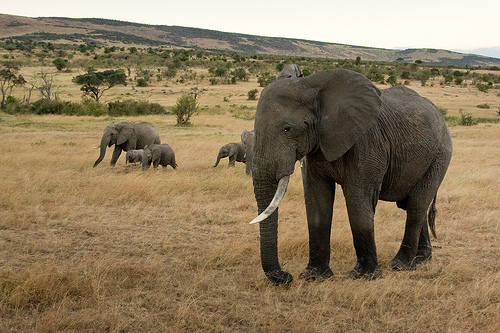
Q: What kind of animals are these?
A: Elephants.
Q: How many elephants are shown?
A: 6.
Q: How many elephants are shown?
A: Four.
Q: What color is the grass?
A: Brown.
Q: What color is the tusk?
A: White.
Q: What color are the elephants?
A: Grey.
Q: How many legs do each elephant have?
A: Four.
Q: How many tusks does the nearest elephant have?
A: One.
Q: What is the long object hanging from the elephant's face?
A: Trunk.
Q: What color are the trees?
A: Green.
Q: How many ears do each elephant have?
A: Two.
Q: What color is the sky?
A: White.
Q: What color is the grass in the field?
A: Brown.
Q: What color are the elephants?
A: Gray.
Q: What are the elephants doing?
A: Walking in the field.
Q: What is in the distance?
A: A large hill.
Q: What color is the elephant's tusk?
A: Ivory.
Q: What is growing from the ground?
A: Shrubs and vegetation.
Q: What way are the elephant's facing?
A: Left.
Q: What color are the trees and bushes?
A: Green.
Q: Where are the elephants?
A: In a pasture.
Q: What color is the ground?
A: Brown.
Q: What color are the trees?
A: Green.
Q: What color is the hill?
A: Brown.